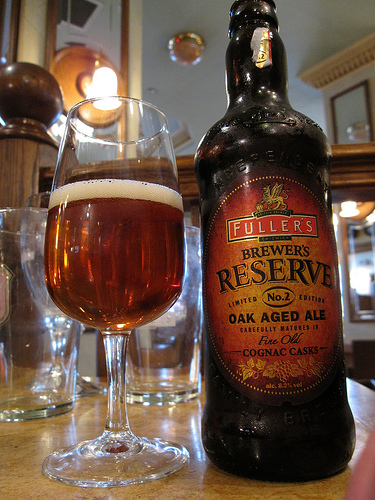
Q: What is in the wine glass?
A: Beer.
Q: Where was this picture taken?
A: At a bar.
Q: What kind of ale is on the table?
A: Fullers.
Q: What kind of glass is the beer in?
A: Wine glass.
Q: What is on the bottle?
A: Label.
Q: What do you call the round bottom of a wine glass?
A: Base.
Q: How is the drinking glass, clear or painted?
A: Clear.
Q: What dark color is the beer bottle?
A: Brown.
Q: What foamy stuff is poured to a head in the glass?
A: Beer.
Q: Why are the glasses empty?
A: No liquid in them.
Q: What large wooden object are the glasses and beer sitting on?
A: Table.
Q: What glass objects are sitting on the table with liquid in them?
A: Glasses.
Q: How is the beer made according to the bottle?
A: Brewed.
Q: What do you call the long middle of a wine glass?
A: Stem.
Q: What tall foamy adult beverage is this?
A: Beer.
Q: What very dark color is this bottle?
A: Black,.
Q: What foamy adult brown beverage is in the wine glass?
A: Beer.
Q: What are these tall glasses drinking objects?
A: Glasses.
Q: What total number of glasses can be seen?
A: Three.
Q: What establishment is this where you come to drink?
A: Bar.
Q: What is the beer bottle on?
A: Table.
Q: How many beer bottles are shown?
A: One.